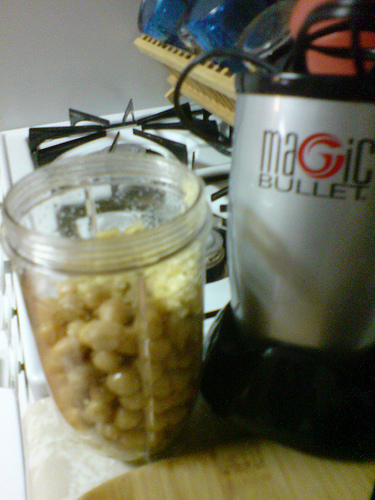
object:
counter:
[21, 386, 183, 500]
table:
[17, 393, 216, 498]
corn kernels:
[134, 310, 163, 341]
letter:
[328, 180, 349, 201]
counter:
[0, 103, 347, 399]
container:
[0, 145, 226, 465]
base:
[201, 304, 375, 468]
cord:
[171, 1, 374, 111]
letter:
[294, 173, 310, 197]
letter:
[347, 179, 373, 204]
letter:
[328, 176, 353, 206]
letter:
[307, 177, 331, 204]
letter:
[273, 174, 296, 200]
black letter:
[343, 135, 355, 188]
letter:
[259, 125, 283, 172]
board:
[75, 443, 375, 499]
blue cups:
[178, 0, 244, 53]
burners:
[24, 93, 231, 182]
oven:
[0, 105, 235, 394]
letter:
[280, 129, 299, 180]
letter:
[342, 133, 357, 187]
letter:
[350, 134, 373, 191]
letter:
[256, 172, 272, 195]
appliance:
[198, 0, 375, 466]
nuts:
[102, 367, 141, 401]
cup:
[134, 0, 191, 44]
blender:
[225, 77, 374, 364]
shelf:
[135, 39, 242, 100]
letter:
[309, 182, 330, 200]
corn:
[76, 317, 122, 355]